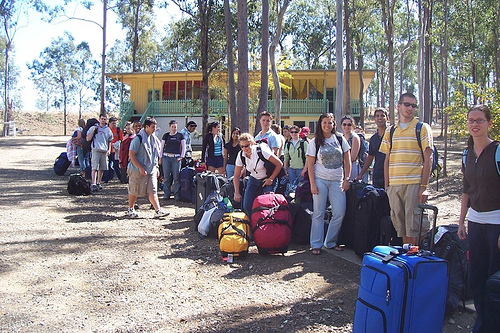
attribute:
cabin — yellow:
[102, 67, 379, 136]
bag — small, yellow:
[218, 206, 251, 259]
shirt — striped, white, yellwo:
[372, 115, 434, 196]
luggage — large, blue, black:
[353, 242, 449, 333]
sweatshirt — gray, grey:
[133, 125, 165, 171]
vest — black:
[460, 140, 500, 214]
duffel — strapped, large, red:
[251, 191, 295, 254]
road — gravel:
[1, 137, 438, 332]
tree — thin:
[28, 28, 84, 136]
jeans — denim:
[305, 178, 348, 251]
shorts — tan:
[120, 160, 162, 198]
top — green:
[282, 134, 311, 169]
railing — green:
[151, 98, 328, 116]